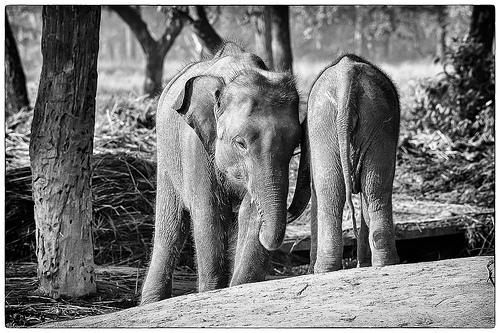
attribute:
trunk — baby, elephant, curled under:
[249, 155, 289, 252]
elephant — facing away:
[288, 47, 412, 275]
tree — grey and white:
[28, 9, 101, 298]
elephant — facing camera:
[117, 28, 309, 310]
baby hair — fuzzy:
[221, 55, 306, 107]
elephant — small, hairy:
[130, 36, 304, 308]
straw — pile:
[15, 118, 167, 246]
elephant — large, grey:
[285, 54, 399, 274]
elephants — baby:
[144, 55, 426, 288]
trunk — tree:
[28, 5, 99, 300]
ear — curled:
[168, 69, 238, 164]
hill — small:
[260, 265, 497, 326]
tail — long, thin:
[338, 60, 360, 237]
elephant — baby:
[167, 29, 316, 274]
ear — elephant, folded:
[173, 71, 243, 151]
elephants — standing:
[194, 80, 399, 230]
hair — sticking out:
[241, 67, 298, 86]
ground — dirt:
[292, 258, 481, 328]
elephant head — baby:
[212, 63, 302, 192]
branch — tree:
[105, 7, 156, 51]